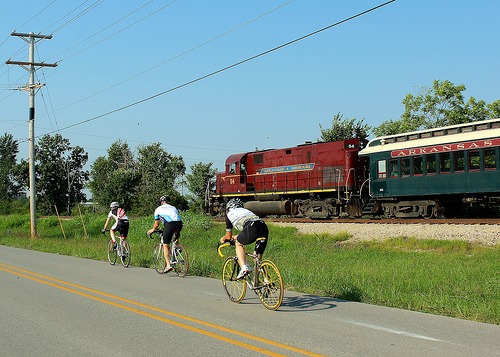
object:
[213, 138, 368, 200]
train engine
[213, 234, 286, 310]
bike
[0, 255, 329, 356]
lines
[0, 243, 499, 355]
road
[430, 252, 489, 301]
patch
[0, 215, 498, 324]
grass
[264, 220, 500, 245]
gravel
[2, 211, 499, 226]
train tracks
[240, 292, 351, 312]
shadow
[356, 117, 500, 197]
train car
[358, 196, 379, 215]
stairs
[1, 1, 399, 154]
powerlines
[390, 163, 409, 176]
passengers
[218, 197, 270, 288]
man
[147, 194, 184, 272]
man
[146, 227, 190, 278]
bike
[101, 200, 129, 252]
man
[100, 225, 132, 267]
bike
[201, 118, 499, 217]
train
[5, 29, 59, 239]
telephone pole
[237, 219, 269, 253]
shorts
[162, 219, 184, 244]
shorts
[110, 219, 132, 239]
shorts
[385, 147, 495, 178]
windows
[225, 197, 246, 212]
helmet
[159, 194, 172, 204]
helmet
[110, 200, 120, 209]
helmet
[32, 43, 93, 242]
wires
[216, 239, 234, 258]
handlebar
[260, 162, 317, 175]
writing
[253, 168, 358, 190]
railing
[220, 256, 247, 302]
rim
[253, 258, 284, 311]
rim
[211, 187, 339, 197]
stripe